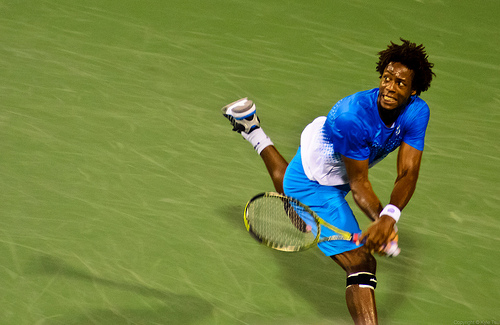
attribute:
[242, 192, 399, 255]
tennis racket — yellow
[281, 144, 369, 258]
shorts — blue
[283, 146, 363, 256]
shorts — Blue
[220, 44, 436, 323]
man — black, playing, looking up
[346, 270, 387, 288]
band — black, white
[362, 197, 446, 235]
band — white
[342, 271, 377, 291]
sweatband — black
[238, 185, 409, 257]
tennis racket — yellow, black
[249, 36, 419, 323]
man — playing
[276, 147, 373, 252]
shorts — blue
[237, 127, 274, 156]
socks — white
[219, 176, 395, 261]
tennis racket — green, black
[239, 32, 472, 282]
player — running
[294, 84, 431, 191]
shirt — blue, white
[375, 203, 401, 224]
sweat band — white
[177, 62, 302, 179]
shoes — white, blue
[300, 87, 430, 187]
shirt — blue, white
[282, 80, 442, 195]
shirt — blue, white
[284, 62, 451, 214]
shirt — Blue, white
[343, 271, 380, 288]
strap — black, white